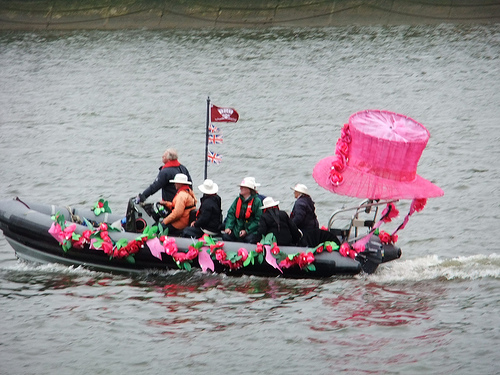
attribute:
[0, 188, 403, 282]
boat — black, small, festive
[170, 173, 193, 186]
hat — white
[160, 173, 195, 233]
woman — steering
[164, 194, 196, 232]
jacket — orange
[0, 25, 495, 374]
water — blue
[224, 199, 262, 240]
coat — green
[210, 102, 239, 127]
flag — red, white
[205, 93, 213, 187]
pole — black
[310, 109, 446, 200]
hat — large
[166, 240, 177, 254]
flower — pink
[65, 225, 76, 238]
flower — pink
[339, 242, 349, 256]
flower — pink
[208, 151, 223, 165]
flag — british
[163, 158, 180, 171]
scarf — red